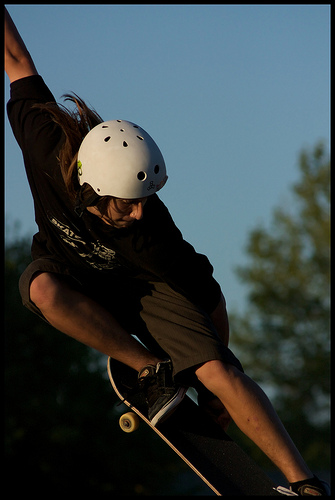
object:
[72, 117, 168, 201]
helmet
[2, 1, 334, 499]
boy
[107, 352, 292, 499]
skateboard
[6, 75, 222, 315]
tshirt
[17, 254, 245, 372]
shorts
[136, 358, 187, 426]
sneakers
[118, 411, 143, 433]
wheels